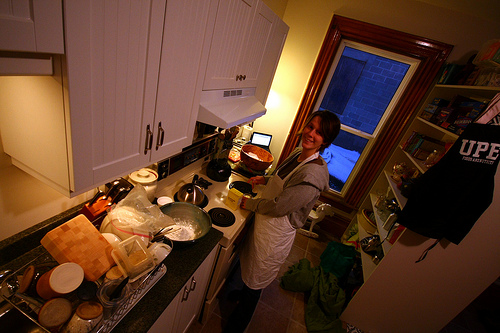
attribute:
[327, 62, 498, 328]
pantry shelves — white, wooden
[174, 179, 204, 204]
kettle — silver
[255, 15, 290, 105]
cabinet — white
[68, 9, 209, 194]
cabinet — white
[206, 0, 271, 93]
cabinet — white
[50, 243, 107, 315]
container — clear, plastic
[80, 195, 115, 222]
block — wooden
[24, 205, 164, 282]
cutting board — light, colored, wooden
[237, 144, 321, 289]
apron — white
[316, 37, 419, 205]
door — glass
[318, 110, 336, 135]
hair — short